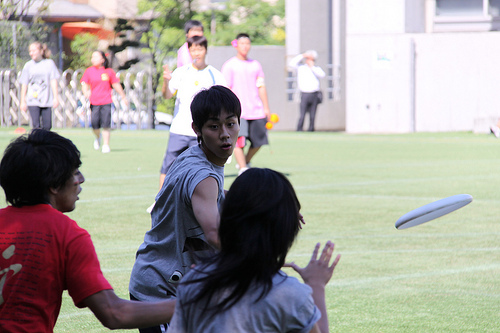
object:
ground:
[1, 124, 500, 333]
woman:
[166, 167, 339, 333]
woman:
[80, 49, 129, 152]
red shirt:
[80, 65, 120, 106]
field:
[0, 124, 500, 333]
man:
[0, 127, 176, 333]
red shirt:
[0, 203, 114, 333]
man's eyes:
[209, 122, 235, 130]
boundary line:
[326, 262, 499, 288]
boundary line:
[342, 247, 499, 255]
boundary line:
[102, 265, 133, 273]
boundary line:
[298, 192, 433, 203]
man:
[293, 52, 326, 131]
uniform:
[287, 55, 325, 130]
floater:
[395, 194, 472, 229]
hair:
[0, 128, 82, 207]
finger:
[291, 240, 341, 271]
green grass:
[0, 133, 499, 333]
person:
[18, 42, 61, 132]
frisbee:
[395, 192, 473, 230]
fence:
[3, 70, 161, 129]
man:
[221, 33, 272, 177]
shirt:
[222, 56, 268, 120]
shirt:
[168, 259, 322, 332]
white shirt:
[168, 64, 227, 136]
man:
[157, 34, 230, 192]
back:
[0, 205, 71, 331]